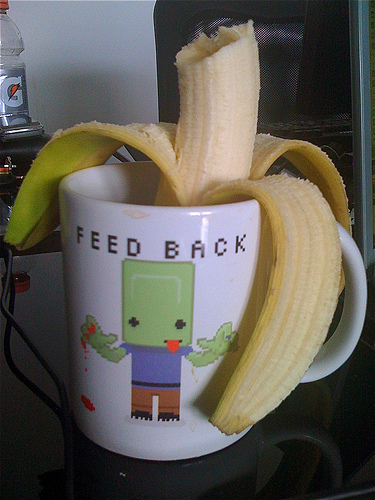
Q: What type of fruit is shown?
A: Banana.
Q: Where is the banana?
A: In a cup.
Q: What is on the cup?
A: A figure.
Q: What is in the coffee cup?
A: Peeled banana.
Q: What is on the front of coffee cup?
A: Green monster.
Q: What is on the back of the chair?
A: Black mesh lumbar support.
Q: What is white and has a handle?
A: A coffee mug.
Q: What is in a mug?
A: The banana.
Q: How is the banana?
A: It is bitten.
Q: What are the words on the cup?
A: Feed back.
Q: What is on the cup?
A: There is a cartoon zombie.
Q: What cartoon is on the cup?
A: Video game zombie.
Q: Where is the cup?
A: On a black desk.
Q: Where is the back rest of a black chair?
A: Behind the table.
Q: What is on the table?
A: A white coffee mug with banana in it.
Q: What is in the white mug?
A: A peeled and bitten banana.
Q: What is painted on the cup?
A: A green skin monster.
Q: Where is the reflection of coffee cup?
A: On the table.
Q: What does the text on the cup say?
A: Feedback.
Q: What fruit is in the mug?
A: Banana.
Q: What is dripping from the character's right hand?
A: Blood.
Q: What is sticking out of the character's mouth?
A: Tongue.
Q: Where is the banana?
A: In the cup.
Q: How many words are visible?
A: Two.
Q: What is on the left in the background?
A: Gatorade Bottle.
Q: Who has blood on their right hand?
A: The Zombie.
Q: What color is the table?
A: Black.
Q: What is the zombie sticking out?
A: Tongue.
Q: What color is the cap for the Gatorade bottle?
A: Orange.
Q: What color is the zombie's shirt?
A: Blue.